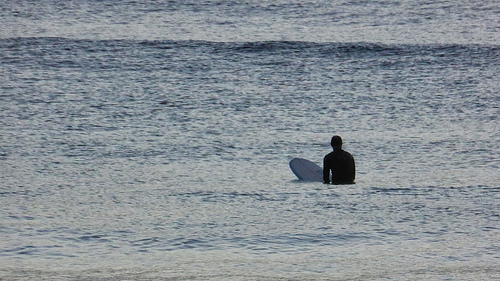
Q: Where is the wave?
A: Out in the water.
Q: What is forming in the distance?
A: Ocean wave.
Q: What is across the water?
A: Ripples.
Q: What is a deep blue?
A: The water.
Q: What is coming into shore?
A: Ocean wave.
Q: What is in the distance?
A: Ocean wave.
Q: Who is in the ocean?
A: A surfer.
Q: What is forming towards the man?
A: A wave.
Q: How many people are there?
A: One.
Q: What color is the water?
A: Blue.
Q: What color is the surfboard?
A: White.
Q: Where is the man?
A: In water.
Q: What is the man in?
A: Water.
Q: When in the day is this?
A: When it's daylight.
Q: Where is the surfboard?
A: Next to the man.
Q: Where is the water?
A: Around the man.